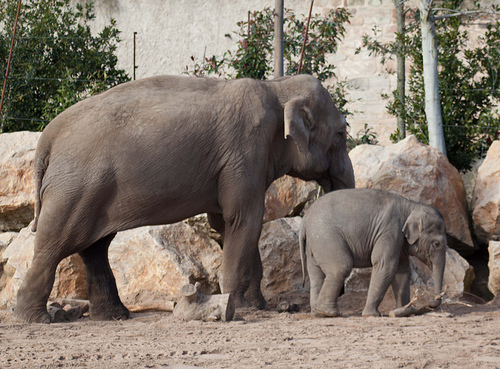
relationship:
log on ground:
[173, 284, 235, 323] [2, 306, 500, 368]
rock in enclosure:
[351, 135, 480, 254] [0, 54, 499, 369]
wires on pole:
[4, 39, 132, 133] [133, 31, 136, 85]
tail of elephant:
[29, 137, 52, 234] [11, 33, 357, 326]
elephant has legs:
[299, 185, 448, 318] [300, 244, 354, 323]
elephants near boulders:
[16, 72, 452, 322] [3, 131, 258, 335]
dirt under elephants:
[0, 309, 498, 367] [16, 72, 452, 322]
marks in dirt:
[6, 344, 227, 362] [0, 309, 498, 367]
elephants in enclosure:
[16, 72, 452, 322] [0, 54, 499, 369]